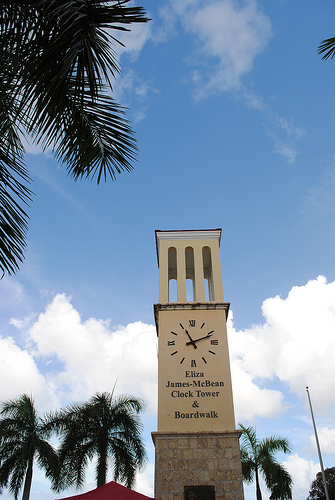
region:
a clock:
[100, 237, 283, 495]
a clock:
[160, 291, 268, 492]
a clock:
[178, 277, 232, 410]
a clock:
[90, 113, 246, 440]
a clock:
[127, 220, 216, 452]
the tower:
[154, 226, 244, 495]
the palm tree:
[62, 393, 135, 481]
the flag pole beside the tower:
[301, 381, 331, 497]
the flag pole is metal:
[297, 382, 333, 497]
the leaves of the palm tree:
[46, 387, 140, 484]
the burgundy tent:
[64, 476, 150, 498]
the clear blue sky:
[157, 130, 249, 193]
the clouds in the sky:
[264, 289, 329, 382]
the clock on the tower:
[160, 318, 225, 373]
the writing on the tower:
[173, 369, 225, 424]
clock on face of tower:
[162, 315, 220, 369]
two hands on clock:
[177, 323, 213, 352]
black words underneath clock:
[168, 357, 223, 426]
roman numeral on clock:
[160, 334, 176, 348]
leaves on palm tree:
[67, 392, 143, 467]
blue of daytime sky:
[163, 124, 230, 190]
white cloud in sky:
[269, 284, 320, 348]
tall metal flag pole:
[298, 380, 322, 455]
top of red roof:
[96, 476, 134, 496]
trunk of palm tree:
[19, 464, 37, 497]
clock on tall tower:
[167, 312, 223, 369]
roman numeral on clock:
[186, 317, 198, 329]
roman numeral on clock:
[199, 320, 206, 333]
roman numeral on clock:
[206, 337, 223, 346]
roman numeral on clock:
[205, 346, 217, 355]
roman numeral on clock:
[200, 356, 209, 366]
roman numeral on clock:
[186, 356, 197, 368]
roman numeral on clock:
[179, 355, 186, 366]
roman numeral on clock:
[168, 348, 178, 358]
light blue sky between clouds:
[146, 137, 207, 197]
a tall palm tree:
[38, 395, 152, 495]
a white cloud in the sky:
[25, 289, 157, 413]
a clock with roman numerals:
[166, 317, 219, 368]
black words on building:
[160, 364, 228, 419]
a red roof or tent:
[52, 478, 156, 498]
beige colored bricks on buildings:
[150, 431, 243, 498]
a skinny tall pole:
[302, 385, 331, 498]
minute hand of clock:
[179, 333, 212, 345]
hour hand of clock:
[183, 326, 199, 348]